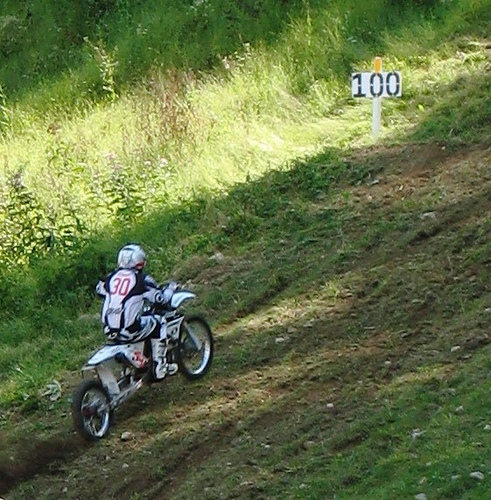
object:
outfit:
[91, 268, 182, 383]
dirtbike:
[70, 272, 225, 446]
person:
[92, 243, 182, 382]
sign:
[349, 56, 406, 142]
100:
[349, 71, 404, 98]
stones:
[417, 207, 439, 234]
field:
[0, 123, 490, 498]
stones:
[447, 338, 468, 354]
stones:
[469, 468, 489, 483]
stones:
[118, 431, 134, 441]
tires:
[71, 381, 112, 443]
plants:
[2, 227, 27, 276]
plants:
[103, 152, 142, 225]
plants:
[137, 151, 173, 198]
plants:
[182, 104, 201, 141]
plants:
[59, 189, 95, 240]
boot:
[149, 325, 179, 382]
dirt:
[158, 465, 187, 484]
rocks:
[383, 359, 391, 367]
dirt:
[326, 401, 333, 409]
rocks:
[273, 334, 287, 344]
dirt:
[408, 237, 420, 250]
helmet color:
[116, 243, 146, 269]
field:
[1, 1, 490, 146]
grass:
[2, 5, 346, 159]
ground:
[216, 148, 488, 498]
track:
[4, 53, 490, 495]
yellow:
[374, 57, 384, 73]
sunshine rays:
[1, 39, 351, 244]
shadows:
[2, 3, 451, 50]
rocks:
[209, 251, 226, 265]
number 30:
[109, 277, 132, 297]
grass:
[296, 360, 490, 498]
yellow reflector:
[373, 55, 381, 71]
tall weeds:
[1, 82, 45, 148]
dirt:
[3, 430, 83, 490]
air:
[3, 408, 82, 492]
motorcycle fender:
[80, 346, 131, 372]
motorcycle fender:
[170, 290, 197, 308]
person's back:
[96, 271, 152, 340]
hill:
[2, 1, 488, 498]